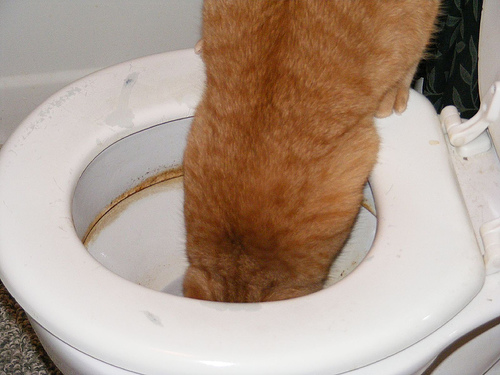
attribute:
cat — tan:
[177, 2, 447, 305]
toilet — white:
[0, 0, 494, 373]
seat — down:
[4, 41, 477, 373]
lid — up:
[476, 1, 500, 160]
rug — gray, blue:
[0, 283, 58, 374]